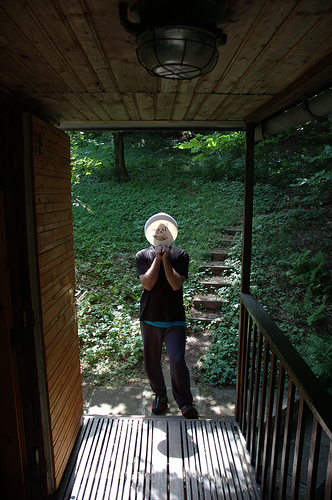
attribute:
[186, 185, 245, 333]
steps — cement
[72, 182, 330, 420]
hill — green, of ivy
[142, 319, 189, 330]
undershirt — blue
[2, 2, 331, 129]
ceiling — wooden, part of a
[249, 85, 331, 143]
gutter — rain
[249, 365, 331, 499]
stands — part of , wooden, some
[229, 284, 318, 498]
rail — wood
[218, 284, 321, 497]
porch railing — brown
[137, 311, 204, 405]
sweat pants — navy blue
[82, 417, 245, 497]
floor — wooden, part of a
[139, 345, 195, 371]
knee — part of a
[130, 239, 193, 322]
t shirt — part of a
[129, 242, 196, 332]
t shirt — part of a